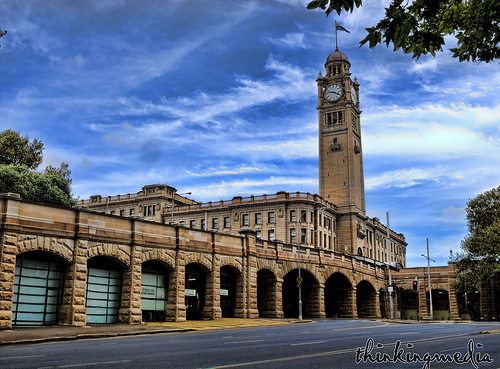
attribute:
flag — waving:
[333, 17, 349, 33]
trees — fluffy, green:
[0, 128, 77, 203]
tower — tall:
[316, 50, 364, 210]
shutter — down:
[13, 255, 61, 327]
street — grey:
[138, 300, 485, 355]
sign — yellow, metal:
[294, 273, 304, 285]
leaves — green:
[450, 177, 497, 239]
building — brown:
[5, 185, 499, 337]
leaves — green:
[490, 187, 494, 292]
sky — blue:
[58, 14, 209, 111]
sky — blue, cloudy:
[1, 0, 499, 267]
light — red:
[407, 233, 435, 335]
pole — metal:
[420, 232, 441, 322]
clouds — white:
[219, 74, 308, 159]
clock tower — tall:
[313, 45, 378, 217]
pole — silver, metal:
[423, 238, 441, 320]